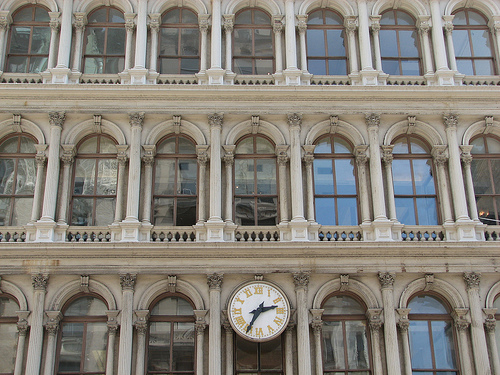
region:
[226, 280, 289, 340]
clock with Roman numerals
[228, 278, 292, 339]
white clock face with yellow numbers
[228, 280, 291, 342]
clock showing 2:35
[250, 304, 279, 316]
hour hand of clock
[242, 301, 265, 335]
black minute hand of clock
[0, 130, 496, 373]
stone building with many arched windows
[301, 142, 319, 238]
pillar supporting window arch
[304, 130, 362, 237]
window with wood separators between panes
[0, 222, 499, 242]
balustrade around upper story of building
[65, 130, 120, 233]
arched window with six panes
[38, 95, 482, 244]
all these windows have arches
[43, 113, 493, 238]
they are all very ornate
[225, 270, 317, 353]
the clock is in the center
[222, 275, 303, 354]
the clock reads 25 til 3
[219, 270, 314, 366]
the numerals are in roman script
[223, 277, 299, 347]
the numerals are gold in color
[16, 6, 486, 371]
the building is mainly white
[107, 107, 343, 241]
the posts hold up the next floor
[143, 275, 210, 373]
the window frames are brown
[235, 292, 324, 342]
the hands of the clock are black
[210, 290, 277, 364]
a clock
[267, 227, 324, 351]
a clock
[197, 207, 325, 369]
a clock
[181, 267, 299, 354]
a clock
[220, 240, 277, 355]
a clock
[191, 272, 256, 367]
a clock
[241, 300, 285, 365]
a clock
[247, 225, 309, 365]
a clock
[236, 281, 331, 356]
clock in front of building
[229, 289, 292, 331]
clock uses roman numerals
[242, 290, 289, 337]
roman numerals are gold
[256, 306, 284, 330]
hands on clock are black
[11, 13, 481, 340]
all windows have arches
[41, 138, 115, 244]
brown frames around windows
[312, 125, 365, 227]
blue sky reflects in windows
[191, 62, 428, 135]
tan balconies on each floor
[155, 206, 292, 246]
decorative railings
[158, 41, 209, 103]
boxes in windows